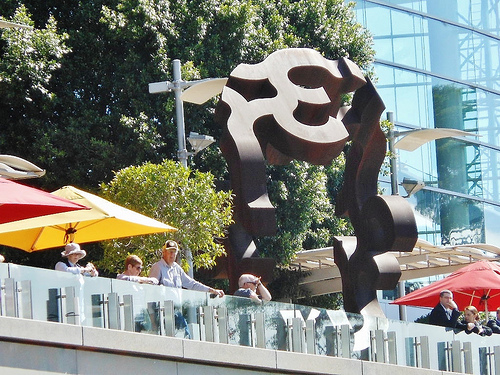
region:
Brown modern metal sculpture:
[218, 42, 400, 317]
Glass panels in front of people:
[111, 282, 242, 342]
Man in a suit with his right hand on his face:
[429, 286, 463, 332]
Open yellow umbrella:
[58, 182, 176, 249]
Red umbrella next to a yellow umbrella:
[0, 175, 82, 224]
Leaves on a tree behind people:
[85, 160, 238, 267]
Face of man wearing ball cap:
[155, 237, 183, 264]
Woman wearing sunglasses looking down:
[121, 256, 148, 278]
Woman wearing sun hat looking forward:
[59, 240, 92, 262]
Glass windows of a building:
[368, 6, 498, 229]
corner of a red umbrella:
[0, 170, 93, 230]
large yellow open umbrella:
[3, 181, 179, 252]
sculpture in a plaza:
[201, 41, 423, 327]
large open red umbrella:
[391, 256, 498, 312]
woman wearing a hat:
[51, 240, 101, 294]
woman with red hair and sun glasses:
[110, 249, 159, 289]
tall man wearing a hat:
[153, 236, 223, 315]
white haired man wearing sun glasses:
[232, 270, 275, 309]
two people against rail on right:
[425, 287, 493, 337]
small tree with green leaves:
[96, 156, 238, 291]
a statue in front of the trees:
[176, 51, 420, 323]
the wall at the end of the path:
[4, 259, 495, 374]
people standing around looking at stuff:
[61, 242, 276, 306]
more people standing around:
[418, 292, 498, 335]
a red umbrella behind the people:
[398, 261, 498, 311]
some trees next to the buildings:
[1, 5, 373, 282]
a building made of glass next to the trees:
[342, 5, 497, 250]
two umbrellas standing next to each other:
[0, 176, 175, 257]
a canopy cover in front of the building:
[282, 236, 497, 292]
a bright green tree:
[87, 165, 228, 262]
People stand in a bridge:
[44, 225, 496, 339]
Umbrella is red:
[2, 174, 83, 229]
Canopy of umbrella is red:
[381, 254, 498, 306]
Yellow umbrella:
[10, 178, 175, 260]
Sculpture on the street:
[191, 32, 423, 333]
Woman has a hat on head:
[55, 238, 102, 280]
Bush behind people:
[98, 150, 236, 252]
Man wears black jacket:
[418, 284, 465, 334]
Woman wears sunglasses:
[232, 261, 276, 311]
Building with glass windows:
[364, 8, 491, 220]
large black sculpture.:
[200, 34, 427, 339]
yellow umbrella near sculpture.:
[3, 139, 198, 279]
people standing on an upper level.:
[38, 186, 238, 305]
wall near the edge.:
[72, 270, 262, 342]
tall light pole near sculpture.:
[144, 11, 206, 204]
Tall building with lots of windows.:
[334, 3, 496, 271]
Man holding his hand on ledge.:
[157, 230, 217, 313]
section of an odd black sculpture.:
[167, 41, 346, 211]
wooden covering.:
[367, 241, 455, 298]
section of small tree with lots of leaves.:
[131, 160, 161, 198]